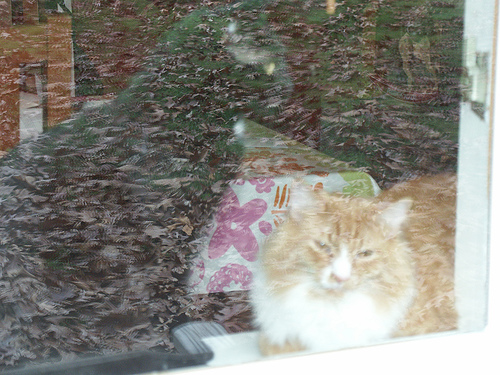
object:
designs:
[205, 184, 275, 305]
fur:
[270, 287, 340, 344]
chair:
[0, 0, 79, 152]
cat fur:
[396, 263, 448, 312]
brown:
[321, 195, 383, 239]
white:
[288, 300, 388, 348]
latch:
[458, 53, 486, 117]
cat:
[0, 0, 298, 367]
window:
[0, 0, 500, 374]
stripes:
[334, 217, 342, 238]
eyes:
[311, 238, 333, 256]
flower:
[206, 188, 267, 262]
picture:
[0, 0, 500, 374]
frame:
[453, 2, 493, 346]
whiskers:
[284, 264, 319, 276]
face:
[271, 195, 399, 294]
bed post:
[42, 12, 75, 128]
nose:
[329, 272, 350, 283]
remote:
[174, 315, 229, 356]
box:
[183, 112, 385, 299]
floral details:
[204, 180, 267, 262]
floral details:
[206, 261, 251, 293]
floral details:
[246, 173, 277, 193]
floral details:
[280, 156, 313, 175]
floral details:
[337, 168, 369, 197]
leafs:
[135, 188, 181, 229]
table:
[203, 328, 265, 365]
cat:
[247, 172, 471, 358]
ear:
[312, 181, 331, 211]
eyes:
[355, 249, 376, 260]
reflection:
[0, 0, 447, 375]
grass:
[55, 120, 165, 264]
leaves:
[31, 229, 80, 257]